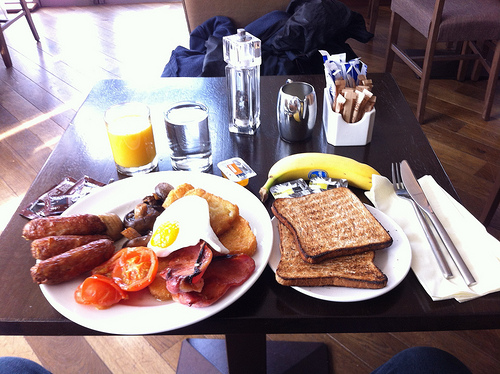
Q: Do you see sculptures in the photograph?
A: No, there are no sculptures.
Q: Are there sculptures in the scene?
A: No, there are no sculptures.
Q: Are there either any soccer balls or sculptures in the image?
A: No, there are no sculptures or soccer balls.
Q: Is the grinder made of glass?
A: Yes, the grinder is made of glass.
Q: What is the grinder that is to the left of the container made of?
A: The grinder is made of glass.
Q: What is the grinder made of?
A: The grinder is made of glass.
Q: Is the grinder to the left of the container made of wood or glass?
A: The shaker is made of glass.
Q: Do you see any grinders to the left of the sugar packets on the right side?
A: Yes, there is a grinder to the left of the sugar packets.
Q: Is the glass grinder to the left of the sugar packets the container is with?
A: Yes, the shaker is to the left of the sugar packets.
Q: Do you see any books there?
A: No, there are no books.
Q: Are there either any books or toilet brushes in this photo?
A: No, there are no books or toilet brushes.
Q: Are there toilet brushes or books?
A: No, there are no books or toilet brushes.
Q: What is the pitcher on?
A: The pitcher is on the table.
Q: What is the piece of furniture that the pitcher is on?
A: The piece of furniture is a table.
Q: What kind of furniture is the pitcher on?
A: The pitcher is on the table.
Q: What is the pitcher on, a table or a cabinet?
A: The pitcher is on a table.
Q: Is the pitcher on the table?
A: Yes, the pitcher is on the table.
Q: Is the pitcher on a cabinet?
A: No, the pitcher is on the table.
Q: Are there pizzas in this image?
A: No, there are no pizzas.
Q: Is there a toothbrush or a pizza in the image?
A: No, there are no pizzas or toothbrushes.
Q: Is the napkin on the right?
A: Yes, the napkin is on the right of the image.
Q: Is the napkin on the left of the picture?
A: No, the napkin is on the right of the image.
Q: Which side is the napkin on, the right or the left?
A: The napkin is on the right of the image.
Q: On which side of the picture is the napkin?
A: The napkin is on the right of the image.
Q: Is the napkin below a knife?
A: Yes, the napkin is below a knife.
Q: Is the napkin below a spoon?
A: No, the napkin is below a knife.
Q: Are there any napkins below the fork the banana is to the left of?
A: Yes, there is a napkin below the fork.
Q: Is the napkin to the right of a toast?
A: Yes, the napkin is to the right of a toast.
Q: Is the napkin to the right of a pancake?
A: No, the napkin is to the right of a toast.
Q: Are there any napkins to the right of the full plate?
A: Yes, there is a napkin to the right of the plate.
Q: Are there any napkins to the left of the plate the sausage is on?
A: No, the napkin is to the right of the plate.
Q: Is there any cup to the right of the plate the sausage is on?
A: No, there is a napkin to the right of the plate.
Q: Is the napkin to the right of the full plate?
A: Yes, the napkin is to the right of the plate.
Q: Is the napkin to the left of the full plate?
A: No, the napkin is to the right of the plate.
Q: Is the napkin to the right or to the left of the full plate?
A: The napkin is to the right of the plate.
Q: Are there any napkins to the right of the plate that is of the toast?
A: Yes, there is a napkin to the right of the plate.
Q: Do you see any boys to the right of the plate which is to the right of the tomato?
A: No, there is a napkin to the right of the plate.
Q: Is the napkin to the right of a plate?
A: Yes, the napkin is to the right of a plate.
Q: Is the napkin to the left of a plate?
A: No, the napkin is to the right of a plate.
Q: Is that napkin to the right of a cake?
A: No, the napkin is to the right of the toast.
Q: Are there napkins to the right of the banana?
A: Yes, there is a napkin to the right of the banana.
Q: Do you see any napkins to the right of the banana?
A: Yes, there is a napkin to the right of the banana.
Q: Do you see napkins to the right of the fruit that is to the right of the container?
A: Yes, there is a napkin to the right of the banana.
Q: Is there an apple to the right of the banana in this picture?
A: No, there is a napkin to the right of the banana.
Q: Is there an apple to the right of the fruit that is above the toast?
A: No, there is a napkin to the right of the banana.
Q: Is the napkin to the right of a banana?
A: Yes, the napkin is to the right of a banana.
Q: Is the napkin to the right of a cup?
A: No, the napkin is to the right of a banana.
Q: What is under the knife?
A: The napkin is under the knife.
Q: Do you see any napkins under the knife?
A: Yes, there is a napkin under the knife.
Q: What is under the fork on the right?
A: The napkin is under the fork.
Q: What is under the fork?
A: The napkin is under the fork.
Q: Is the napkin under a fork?
A: Yes, the napkin is under a fork.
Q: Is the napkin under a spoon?
A: No, the napkin is under a fork.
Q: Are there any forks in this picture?
A: Yes, there is a fork.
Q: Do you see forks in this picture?
A: Yes, there is a fork.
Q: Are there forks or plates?
A: Yes, there is a fork.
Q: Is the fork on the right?
A: Yes, the fork is on the right of the image.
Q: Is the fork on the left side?
A: No, the fork is on the right of the image.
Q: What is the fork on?
A: The fork is on the napkin.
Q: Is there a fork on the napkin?
A: Yes, there is a fork on the napkin.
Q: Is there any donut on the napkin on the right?
A: No, there is a fork on the napkin.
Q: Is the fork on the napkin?
A: Yes, the fork is on the napkin.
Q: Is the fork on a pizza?
A: No, the fork is on the napkin.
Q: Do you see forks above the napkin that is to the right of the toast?
A: Yes, there is a fork above the napkin.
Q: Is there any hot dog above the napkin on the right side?
A: No, there is a fork above the napkin.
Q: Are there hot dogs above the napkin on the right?
A: No, there is a fork above the napkin.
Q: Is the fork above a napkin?
A: Yes, the fork is above a napkin.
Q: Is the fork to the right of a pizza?
A: No, the fork is to the right of a toast.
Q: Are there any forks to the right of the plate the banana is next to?
A: Yes, there is a fork to the right of the plate.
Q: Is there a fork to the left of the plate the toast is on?
A: No, the fork is to the right of the plate.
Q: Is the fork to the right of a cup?
A: No, the fork is to the right of the plate.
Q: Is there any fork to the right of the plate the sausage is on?
A: Yes, there is a fork to the right of the plate.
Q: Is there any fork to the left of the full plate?
A: No, the fork is to the right of the plate.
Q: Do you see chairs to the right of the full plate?
A: No, there is a fork to the right of the plate.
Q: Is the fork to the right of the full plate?
A: Yes, the fork is to the right of the plate.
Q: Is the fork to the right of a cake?
A: No, the fork is to the right of the plate.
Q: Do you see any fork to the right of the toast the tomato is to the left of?
A: Yes, there is a fork to the right of the toast.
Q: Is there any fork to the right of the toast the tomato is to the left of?
A: Yes, there is a fork to the right of the toast.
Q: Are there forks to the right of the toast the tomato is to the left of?
A: Yes, there is a fork to the right of the toast.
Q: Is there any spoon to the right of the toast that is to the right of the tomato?
A: No, there is a fork to the right of the toast.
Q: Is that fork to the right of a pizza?
A: No, the fork is to the right of a toast.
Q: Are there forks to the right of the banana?
A: Yes, there is a fork to the right of the banana.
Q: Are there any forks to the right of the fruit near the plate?
A: Yes, there is a fork to the right of the banana.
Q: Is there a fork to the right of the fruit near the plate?
A: Yes, there is a fork to the right of the banana.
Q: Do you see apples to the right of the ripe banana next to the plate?
A: No, there is a fork to the right of the banana.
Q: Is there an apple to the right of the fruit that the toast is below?
A: No, there is a fork to the right of the banana.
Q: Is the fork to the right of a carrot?
A: No, the fork is to the right of the banana.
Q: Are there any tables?
A: Yes, there is a table.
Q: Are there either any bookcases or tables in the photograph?
A: Yes, there is a table.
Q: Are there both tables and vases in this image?
A: No, there is a table but no vases.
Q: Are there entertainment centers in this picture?
A: No, there are no entertainment centers.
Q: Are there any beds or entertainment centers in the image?
A: No, there are no entertainment centers or beds.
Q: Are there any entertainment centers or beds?
A: No, there are no entertainment centers or beds.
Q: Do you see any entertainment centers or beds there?
A: No, there are no entertainment centers or beds.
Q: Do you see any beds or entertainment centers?
A: No, there are no entertainment centers or beds.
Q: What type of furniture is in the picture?
A: The furniture is a table.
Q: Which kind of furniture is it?
A: The piece of furniture is a table.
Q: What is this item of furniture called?
A: This is a table.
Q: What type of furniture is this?
A: This is a table.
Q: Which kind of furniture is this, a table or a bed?
A: This is a table.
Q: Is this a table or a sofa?
A: This is a table.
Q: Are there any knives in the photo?
A: Yes, there is a knife.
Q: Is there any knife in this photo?
A: Yes, there is a knife.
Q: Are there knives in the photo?
A: Yes, there is a knife.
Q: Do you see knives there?
A: Yes, there is a knife.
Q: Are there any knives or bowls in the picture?
A: Yes, there is a knife.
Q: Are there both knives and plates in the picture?
A: Yes, there are both a knife and a plate.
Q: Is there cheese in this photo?
A: No, there is no cheese.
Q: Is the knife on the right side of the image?
A: Yes, the knife is on the right of the image.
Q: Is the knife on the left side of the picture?
A: No, the knife is on the right of the image.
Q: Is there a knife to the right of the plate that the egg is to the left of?
A: Yes, there is a knife to the right of the plate.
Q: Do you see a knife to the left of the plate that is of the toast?
A: No, the knife is to the right of the plate.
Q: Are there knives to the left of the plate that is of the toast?
A: No, the knife is to the right of the plate.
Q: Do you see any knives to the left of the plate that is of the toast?
A: No, the knife is to the right of the plate.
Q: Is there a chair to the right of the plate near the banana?
A: No, there is a knife to the right of the plate.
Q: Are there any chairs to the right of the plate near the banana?
A: No, there is a knife to the right of the plate.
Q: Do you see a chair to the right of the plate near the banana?
A: No, there is a knife to the right of the plate.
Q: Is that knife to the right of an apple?
A: No, the knife is to the right of a plate.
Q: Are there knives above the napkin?
A: Yes, there is a knife above the napkin.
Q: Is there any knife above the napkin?
A: Yes, there is a knife above the napkin.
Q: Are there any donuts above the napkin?
A: No, there is a knife above the napkin.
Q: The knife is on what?
A: The knife is on the napkin.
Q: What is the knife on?
A: The knife is on the napkin.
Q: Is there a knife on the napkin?
A: Yes, there is a knife on the napkin.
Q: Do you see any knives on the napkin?
A: Yes, there is a knife on the napkin.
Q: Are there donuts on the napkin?
A: No, there is a knife on the napkin.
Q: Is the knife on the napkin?
A: Yes, the knife is on the napkin.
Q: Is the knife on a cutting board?
A: No, the knife is on the napkin.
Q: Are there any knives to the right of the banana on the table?
A: Yes, there is a knife to the right of the banana.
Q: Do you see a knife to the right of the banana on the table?
A: Yes, there is a knife to the right of the banana.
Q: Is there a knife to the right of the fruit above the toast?
A: Yes, there is a knife to the right of the banana.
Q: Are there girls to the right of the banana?
A: No, there is a knife to the right of the banana.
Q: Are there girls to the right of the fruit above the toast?
A: No, there is a knife to the right of the banana.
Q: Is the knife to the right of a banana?
A: Yes, the knife is to the right of a banana.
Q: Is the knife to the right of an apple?
A: No, the knife is to the right of a banana.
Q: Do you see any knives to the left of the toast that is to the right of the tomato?
A: No, the knife is to the right of the toast.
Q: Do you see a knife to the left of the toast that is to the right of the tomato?
A: No, the knife is to the right of the toast.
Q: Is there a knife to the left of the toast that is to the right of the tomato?
A: No, the knife is to the right of the toast.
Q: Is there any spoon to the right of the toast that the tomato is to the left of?
A: No, there is a knife to the right of the toast.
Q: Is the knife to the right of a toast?
A: Yes, the knife is to the right of a toast.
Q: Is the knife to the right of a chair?
A: No, the knife is to the right of a toast.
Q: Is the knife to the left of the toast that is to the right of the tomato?
A: No, the knife is to the right of the toast.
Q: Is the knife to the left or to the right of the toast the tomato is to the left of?
A: The knife is to the right of the toast.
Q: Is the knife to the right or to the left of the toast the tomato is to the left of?
A: The knife is to the right of the toast.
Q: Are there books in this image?
A: No, there are no books.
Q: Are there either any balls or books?
A: No, there are no books or balls.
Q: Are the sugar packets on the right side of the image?
A: Yes, the sugar packets are on the right of the image.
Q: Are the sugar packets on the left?
A: No, the sugar packets are on the right of the image.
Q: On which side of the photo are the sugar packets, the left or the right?
A: The sugar packets are on the right of the image.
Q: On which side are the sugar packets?
A: The sugar packets are on the right of the image.